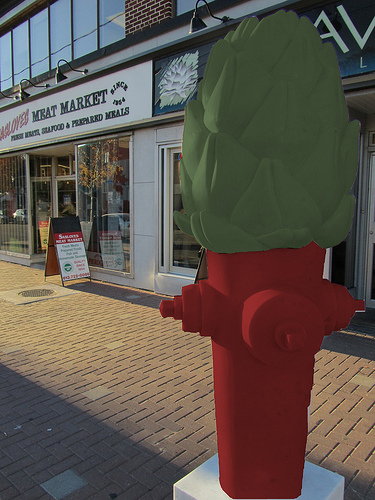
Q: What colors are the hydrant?
A: Red and green.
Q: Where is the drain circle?
A: On sidewalk.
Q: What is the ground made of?
A: Bricks.